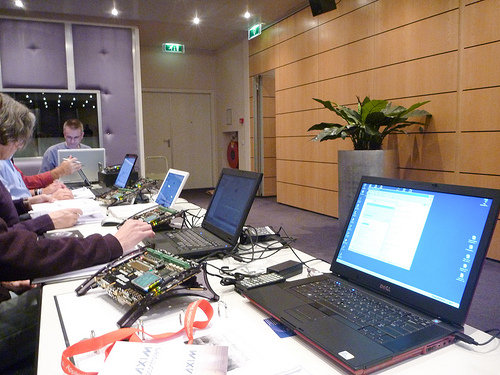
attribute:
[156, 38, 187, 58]
sign — green, white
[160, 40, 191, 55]
sign — exit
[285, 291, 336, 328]
pad — mouse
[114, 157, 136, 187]
screen — open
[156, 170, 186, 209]
screen — open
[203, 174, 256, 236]
screen — open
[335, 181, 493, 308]
screen — open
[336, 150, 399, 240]
silver planter — tall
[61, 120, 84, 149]
head — tilted down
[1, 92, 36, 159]
head — tilted down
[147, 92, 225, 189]
door — white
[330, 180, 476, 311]
screen — open 